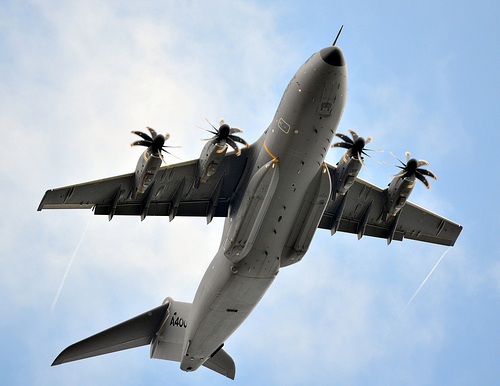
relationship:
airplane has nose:
[32, 27, 464, 382] [317, 47, 345, 71]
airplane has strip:
[32, 27, 464, 382] [255, 136, 279, 171]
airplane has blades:
[32, 27, 464, 382] [129, 125, 174, 154]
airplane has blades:
[32, 27, 464, 382] [205, 118, 241, 148]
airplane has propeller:
[32, 27, 464, 382] [330, 124, 378, 174]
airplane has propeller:
[32, 27, 464, 382] [388, 148, 438, 188]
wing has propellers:
[44, 138, 243, 228] [123, 114, 438, 192]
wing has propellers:
[319, 162, 463, 251] [123, 114, 438, 192]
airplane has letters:
[32, 27, 464, 382] [165, 310, 202, 335]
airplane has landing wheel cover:
[32, 27, 464, 382] [214, 264, 271, 317]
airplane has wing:
[32, 27, 464, 382] [44, 138, 243, 228]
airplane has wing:
[32, 27, 464, 382] [319, 162, 463, 251]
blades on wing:
[129, 125, 174, 154] [44, 138, 243, 228]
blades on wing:
[205, 118, 241, 148] [44, 138, 243, 228]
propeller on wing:
[330, 124, 378, 174] [319, 162, 463, 251]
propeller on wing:
[388, 148, 438, 188] [319, 162, 463, 251]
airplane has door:
[32, 27, 464, 382] [271, 114, 290, 138]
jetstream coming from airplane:
[401, 241, 455, 317] [32, 27, 464, 382]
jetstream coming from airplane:
[45, 205, 115, 312] [32, 27, 464, 382]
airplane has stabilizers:
[32, 27, 464, 382] [222, 152, 335, 273]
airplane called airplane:
[32, 27, 464, 382] [32, 27, 464, 382]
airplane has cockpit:
[32, 27, 464, 382] [276, 47, 350, 128]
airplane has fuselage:
[32, 27, 464, 382] [165, 209, 306, 379]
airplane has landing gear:
[32, 27, 464, 382] [222, 152, 335, 273]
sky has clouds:
[3, 4, 497, 384] [40, 23, 336, 293]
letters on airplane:
[165, 310, 202, 335] [32, 27, 464, 382]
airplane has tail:
[32, 27, 464, 382] [45, 235, 279, 386]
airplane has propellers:
[32, 27, 464, 382] [123, 114, 438, 192]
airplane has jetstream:
[32, 27, 464, 382] [401, 241, 455, 317]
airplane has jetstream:
[32, 27, 464, 382] [45, 205, 115, 312]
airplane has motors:
[32, 27, 464, 382] [123, 114, 438, 192]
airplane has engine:
[32, 27, 464, 382] [330, 124, 378, 174]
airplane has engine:
[32, 27, 464, 382] [388, 148, 438, 188]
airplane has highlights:
[32, 27, 464, 382] [239, 122, 355, 181]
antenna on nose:
[329, 22, 346, 49] [317, 47, 345, 71]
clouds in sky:
[40, 23, 336, 293] [3, 4, 497, 384]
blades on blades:
[129, 125, 174, 154] [129, 125, 174, 154]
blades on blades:
[205, 118, 241, 148] [205, 118, 241, 148]